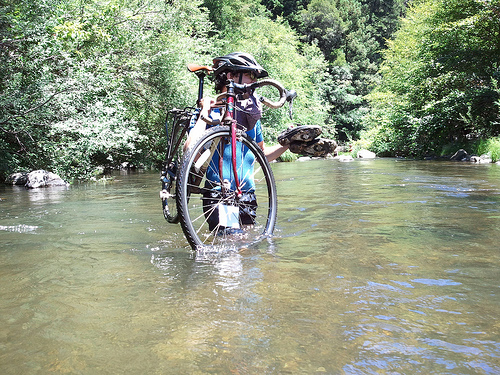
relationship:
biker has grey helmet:
[183, 52, 295, 241] [201, 48, 286, 93]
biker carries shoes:
[183, 53, 291, 230] [282, 124, 337, 154]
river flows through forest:
[0, 157, 500, 373] [1, 0, 496, 185]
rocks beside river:
[11, 169, 69, 189] [0, 157, 500, 373]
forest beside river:
[0, 0, 499, 181] [91, 186, 469, 340]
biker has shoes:
[183, 52, 295, 241] [277, 124, 337, 156]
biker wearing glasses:
[183, 52, 295, 241] [238, 73, 271, 81]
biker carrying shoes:
[183, 52, 295, 241] [265, 115, 351, 158]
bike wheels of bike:
[175, 126, 278, 256] [139, 51, 321, 263]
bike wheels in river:
[175, 126, 278, 256] [0, 156, 499, 374]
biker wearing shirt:
[183, 52, 295, 241] [212, 118, 266, 186]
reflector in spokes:
[192, 143, 212, 170] [192, 137, 273, 252]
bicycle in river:
[158, 62, 298, 257] [0, 156, 499, 374]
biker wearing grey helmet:
[183, 52, 295, 241] [212, 51, 269, 93]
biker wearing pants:
[183, 52, 295, 241] [204, 183, 256, 234]